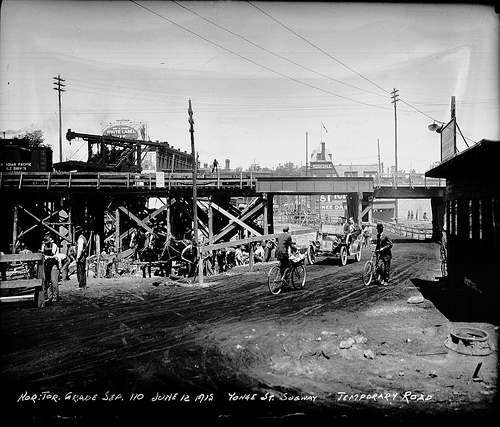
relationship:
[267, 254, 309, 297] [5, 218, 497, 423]
bicycle in road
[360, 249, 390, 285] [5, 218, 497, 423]
bicycle in road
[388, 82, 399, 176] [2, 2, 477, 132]
posts for lines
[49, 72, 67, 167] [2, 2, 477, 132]
posts for lines